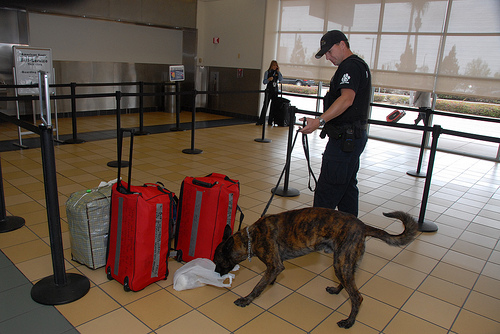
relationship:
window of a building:
[373, 30, 445, 75] [8, 6, 493, 331]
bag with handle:
[104, 126, 175, 291] [97, 85, 158, 190]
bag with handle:
[173, 172, 246, 267] [235, 205, 248, 231]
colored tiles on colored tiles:
[429, 254, 465, 312] [0, 110, 500, 334]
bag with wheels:
[104, 126, 175, 291] [117, 277, 144, 307]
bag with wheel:
[173, 172, 246, 267] [166, 247, 178, 264]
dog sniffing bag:
[208, 207, 418, 328] [173, 257, 236, 290]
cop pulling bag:
[296, 28, 374, 220] [104, 126, 175, 291]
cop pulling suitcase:
[296, 28, 374, 220] [178, 169, 244, 266]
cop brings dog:
[296, 28, 374, 220] [208, 207, 418, 328]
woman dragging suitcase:
[409, 91, 432, 125] [384, 108, 406, 123]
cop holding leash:
[296, 28, 374, 220] [258, 127, 318, 220]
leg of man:
[310, 131, 365, 217] [285, 41, 416, 238]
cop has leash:
[296, 28, 374, 220] [240, 115, 323, 232]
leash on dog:
[240, 115, 323, 232] [199, 196, 417, 332]